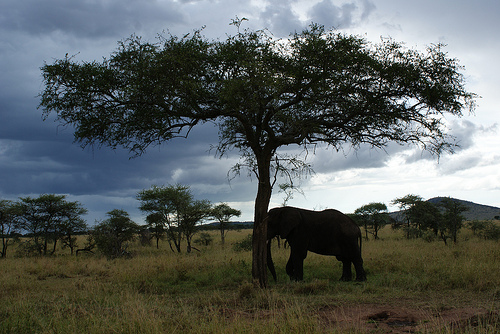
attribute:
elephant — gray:
[270, 204, 371, 286]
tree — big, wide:
[47, 34, 387, 174]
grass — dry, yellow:
[393, 270, 414, 290]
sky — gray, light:
[44, 14, 82, 35]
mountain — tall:
[472, 207, 489, 218]